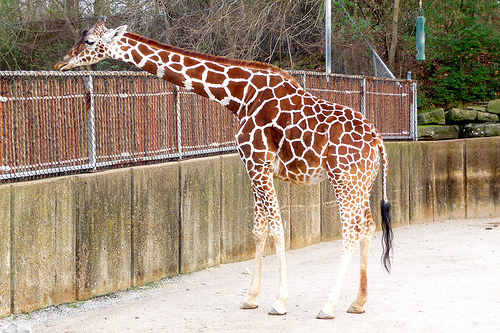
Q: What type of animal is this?
A: Giraffe.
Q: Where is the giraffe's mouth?
A: Hanging over the fence.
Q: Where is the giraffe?
A: Near fence.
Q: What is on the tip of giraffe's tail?
A: Black hair.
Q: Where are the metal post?
A: On fence.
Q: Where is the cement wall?
A: Under the fence.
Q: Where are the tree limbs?
A: Behind the fence.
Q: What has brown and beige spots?
A: The giraffe.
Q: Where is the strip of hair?
A: Along neckline.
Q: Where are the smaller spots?
A: Along the legs.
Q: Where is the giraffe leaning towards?
A: The fence.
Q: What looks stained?
A: The wall.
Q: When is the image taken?
A: Giraffe looks outside the fence.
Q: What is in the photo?
A: Giraffe.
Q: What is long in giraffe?
A: Neck.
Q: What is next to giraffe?
A: Fence.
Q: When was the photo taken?
A: Daytime.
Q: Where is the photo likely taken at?
A: Zoo.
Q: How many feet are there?
A: 4.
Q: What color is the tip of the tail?
A: Black.